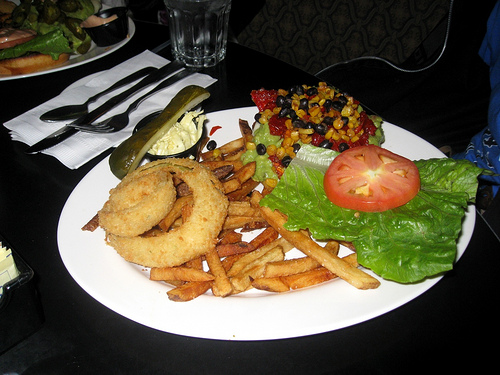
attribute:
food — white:
[116, 113, 430, 283]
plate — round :
[71, 175, 394, 353]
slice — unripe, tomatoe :
[322, 151, 425, 207]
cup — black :
[149, 120, 196, 158]